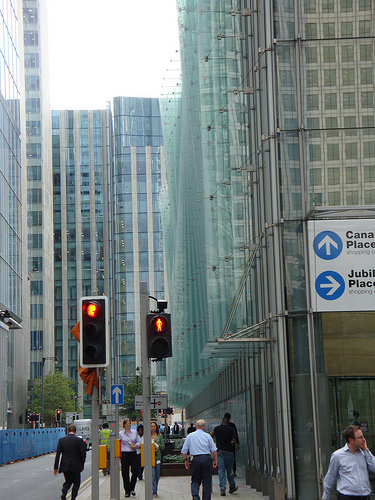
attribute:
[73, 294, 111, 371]
light — traffic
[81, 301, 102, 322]
light — red, lit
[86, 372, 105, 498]
pole — gray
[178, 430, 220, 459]
shirt — blue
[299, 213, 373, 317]
sign — street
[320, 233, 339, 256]
arrow — white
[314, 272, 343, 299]
arrow — white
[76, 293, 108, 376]
light — red, traffic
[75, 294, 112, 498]
pole — silver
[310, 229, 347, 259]
circle — blue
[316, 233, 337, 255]
arrow — white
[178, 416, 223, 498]
man — balding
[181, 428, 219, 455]
shirt — blue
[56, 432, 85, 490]
suit — black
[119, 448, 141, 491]
pants — black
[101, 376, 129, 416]
sign — rectangular, blue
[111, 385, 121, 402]
arrow — white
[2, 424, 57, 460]
barrier — blue, construction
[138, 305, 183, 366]
light fixture — black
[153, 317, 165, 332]
light — red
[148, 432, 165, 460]
shirt — green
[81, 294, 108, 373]
light — traffic, red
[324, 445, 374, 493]
shirt — light blue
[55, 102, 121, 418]
building — tall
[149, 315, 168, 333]
signal — red, no walking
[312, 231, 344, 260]
arrow — pointing straight up